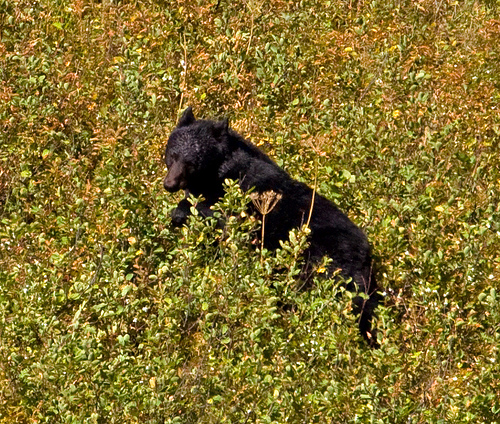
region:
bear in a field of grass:
[135, 95, 400, 332]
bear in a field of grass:
[143, 85, 400, 337]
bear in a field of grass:
[148, 104, 376, 330]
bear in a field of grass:
[133, 97, 390, 348]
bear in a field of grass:
[147, 103, 395, 340]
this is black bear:
[10, 25, 412, 365]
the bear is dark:
[128, 98, 346, 280]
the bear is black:
[93, 110, 369, 312]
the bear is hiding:
[125, 78, 403, 346]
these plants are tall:
[128, 234, 363, 394]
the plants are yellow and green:
[131, 228, 328, 354]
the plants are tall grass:
[116, 227, 332, 351]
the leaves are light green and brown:
[87, 288, 315, 393]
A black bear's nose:
[164, 164, 185, 189]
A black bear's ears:
[179, 105, 230, 135]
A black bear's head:
[163, 106, 230, 193]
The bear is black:
[161, 104, 378, 334]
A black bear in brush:
[163, 105, 383, 348]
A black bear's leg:
[168, 198, 194, 228]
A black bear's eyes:
[167, 149, 194, 168]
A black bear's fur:
[168, 106, 381, 345]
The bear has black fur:
[164, 105, 383, 342]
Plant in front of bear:
[251, 189, 280, 264]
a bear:
[158, 110, 386, 312]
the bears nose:
[158, 178, 178, 195]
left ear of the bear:
[208, 115, 230, 130]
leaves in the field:
[103, 321, 180, 385]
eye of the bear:
[167, 153, 184, 161]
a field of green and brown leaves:
[364, 82, 452, 171]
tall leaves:
[209, 188, 285, 257]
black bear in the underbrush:
[160, 104, 383, 325]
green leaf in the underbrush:
[476, 289, 485, 301]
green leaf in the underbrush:
[198, 297, 208, 310]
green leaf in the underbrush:
[410, 58, 423, 70]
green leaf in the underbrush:
[20, 166, 29, 180]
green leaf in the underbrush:
[117, 332, 127, 347]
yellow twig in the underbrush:
[247, 188, 284, 247]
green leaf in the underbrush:
[363, 370, 373, 385]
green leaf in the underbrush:
[55, 396, 65, 411]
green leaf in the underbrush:
[148, 90, 154, 106]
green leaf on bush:
[271, 385, 280, 398]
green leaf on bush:
[321, 386, 331, 398]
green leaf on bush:
[326, 385, 335, 393]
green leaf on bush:
[369, 346, 384, 356]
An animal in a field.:
[127, 112, 427, 354]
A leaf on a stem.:
[286, 227, 298, 249]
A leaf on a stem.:
[236, 300, 241, 305]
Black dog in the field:
[135, 98, 387, 351]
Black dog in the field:
[151, 102, 378, 345]